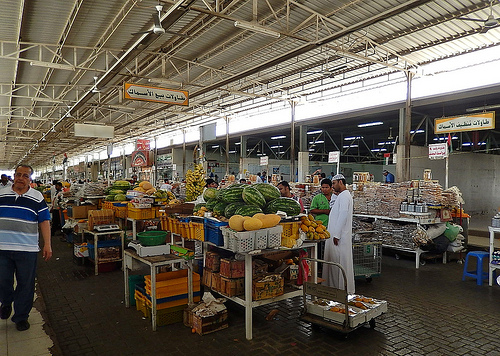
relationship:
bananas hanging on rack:
[171, 162, 221, 203] [189, 159, 201, 200]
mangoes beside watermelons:
[221, 208, 287, 242] [188, 178, 300, 225]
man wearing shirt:
[1, 163, 54, 333] [0, 183, 52, 252]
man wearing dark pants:
[1, 154, 65, 339] [1, 247, 41, 332]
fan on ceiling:
[121, 8, 184, 43] [10, 6, 481, 185]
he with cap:
[321, 174, 357, 295] [327, 171, 344, 181]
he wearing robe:
[321, 174, 357, 295] [325, 188, 356, 293]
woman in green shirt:
[301, 172, 336, 222] [308, 183, 332, 226]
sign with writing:
[122, 82, 189, 107] [128, 85, 189, 106]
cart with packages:
[299, 254, 379, 335] [302, 285, 387, 328]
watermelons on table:
[202, 183, 302, 219] [201, 217, 319, 324]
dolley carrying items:
[300, 256, 392, 337] [349, 293, 378, 315]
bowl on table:
[137, 230, 164, 247] [115, 248, 184, 323]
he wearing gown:
[321, 174, 357, 295] [323, 189, 357, 294]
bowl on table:
[136, 230, 168, 246] [119, 242, 196, 332]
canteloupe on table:
[228, 213, 247, 234] [201, 233, 322, 345]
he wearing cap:
[321, 174, 357, 295] [331, 169, 348, 182]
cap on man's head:
[331, 170, 346, 181] [328, 169, 347, 196]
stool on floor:
[462, 246, 491, 284] [33, 233, 497, 354]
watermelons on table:
[202, 181, 299, 221] [201, 241, 319, 338]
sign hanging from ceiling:
[117, 79, 190, 106] [0, 2, 490, 164]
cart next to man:
[299, 254, 379, 335] [320, 172, 355, 294]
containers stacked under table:
[126, 265, 201, 321] [140, 247, 181, 315]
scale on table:
[126, 238, 171, 257] [121, 248, 195, 331]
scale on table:
[92, 218, 121, 233] [81, 226, 127, 277]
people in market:
[30, 130, 430, 317] [0, 6, 496, 353]